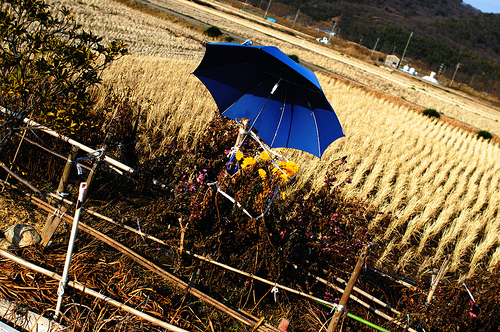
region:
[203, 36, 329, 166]
One umbrella is seen.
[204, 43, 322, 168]
Umbrella is blue color.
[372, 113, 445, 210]
Crops are brown color.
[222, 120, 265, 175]
Umbrella is tied to the pole.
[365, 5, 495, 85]
Mountain is seen behind the picture.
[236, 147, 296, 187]
Flowers are yellow.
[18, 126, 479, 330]
Fence is around the umbrella.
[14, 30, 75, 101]
Plant is green color.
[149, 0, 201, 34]
Road is grey color.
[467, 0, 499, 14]
Sky is blue color.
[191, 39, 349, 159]
a bright and cheerful blue umbrella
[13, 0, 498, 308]
a field of tan colored crops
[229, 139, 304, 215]
bright yellow flowers under the umbrella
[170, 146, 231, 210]
small pink flowers under the umbrella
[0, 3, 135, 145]
a small spindly tree next to the umbrella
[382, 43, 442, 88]
a cluster of buildings on the other side of the field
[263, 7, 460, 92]
electrical poles behind the field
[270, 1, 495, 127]
a hill full of trees behind the field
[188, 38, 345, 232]
the umbrella is open in the sun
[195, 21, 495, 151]
small green shrubs between two fields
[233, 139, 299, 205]
Bunch of yellow flowers near the umbrella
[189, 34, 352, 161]
A large blue umbrella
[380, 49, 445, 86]
Farm buildings off in the distance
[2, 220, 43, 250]
a small rock on the ground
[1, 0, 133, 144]
A green bush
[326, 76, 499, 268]
A brown field of wheat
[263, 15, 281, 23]
A blue building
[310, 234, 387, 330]
Rickety looking fence post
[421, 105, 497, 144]
Green trees in the middle of the field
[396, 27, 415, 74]
A tall power pole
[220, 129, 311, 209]
yellow flowers in dried grass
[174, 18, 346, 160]
a blue umbrella in field of straw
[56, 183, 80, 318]
a white plastic pipe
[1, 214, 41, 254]
a rock on the ground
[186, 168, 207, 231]
pink flowers in a field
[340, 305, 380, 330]
a green pole on the fence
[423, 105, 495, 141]
green shrubs in the distance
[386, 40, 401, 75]
a barn in the distance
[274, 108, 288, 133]
metal spokes in a an umbrella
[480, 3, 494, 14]
the clear blue sky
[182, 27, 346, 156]
an open blue umbrella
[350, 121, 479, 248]
rows of golden-yellow colored plants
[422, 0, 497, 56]
hills in the distance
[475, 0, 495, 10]
a small patch of hazy blue sky in the distance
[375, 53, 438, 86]
buildings in the distance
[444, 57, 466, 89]
utility pole in the distance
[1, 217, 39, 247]
a stone with a shadow on it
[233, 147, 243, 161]
a small yellow flower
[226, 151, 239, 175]
a blue umbrella handle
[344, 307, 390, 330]
a green hose on the ground